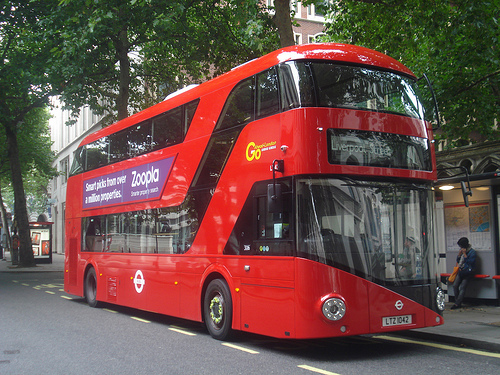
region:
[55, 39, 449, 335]
a red bus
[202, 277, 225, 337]
the front tire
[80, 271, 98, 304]
the back tire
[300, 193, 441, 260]
windshield on the bus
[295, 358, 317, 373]
the white line on the street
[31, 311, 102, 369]
the street is grey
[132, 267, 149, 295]
logo on the bus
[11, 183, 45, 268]
a tree trunk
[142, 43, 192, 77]
the leaves on the tree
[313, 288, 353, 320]
a headlight on the bus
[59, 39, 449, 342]
A double decker bus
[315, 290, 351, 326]
A headlight on a bus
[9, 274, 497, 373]
White lines on the road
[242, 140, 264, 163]
The word "Go" in yellow letters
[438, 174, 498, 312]
A person sitting at a bus stop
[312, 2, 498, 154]
Green leaves on a tree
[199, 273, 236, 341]
A black round tire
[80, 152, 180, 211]
A purple sign with white writing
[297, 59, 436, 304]
Reflections on the front bus windows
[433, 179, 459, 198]
A light is turned on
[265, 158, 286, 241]
the buses side view mirror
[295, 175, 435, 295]
the drivers front windshield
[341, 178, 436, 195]
the buses windshield wiper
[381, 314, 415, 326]
the buses license plate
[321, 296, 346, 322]
the buses round headlights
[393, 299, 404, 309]
the buses name brand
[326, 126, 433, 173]
the bus street name and route number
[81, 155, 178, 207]
an advertising banner displayed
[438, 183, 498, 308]
someone sitting on a bus bench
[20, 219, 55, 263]
a bus stop on the walkway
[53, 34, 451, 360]
A bus in the foreground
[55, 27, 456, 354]
The bus is red in color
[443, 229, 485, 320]
A person in the background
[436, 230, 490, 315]
Person is sitting down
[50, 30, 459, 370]
The bus is a double decker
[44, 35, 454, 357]
The bus is parked on the side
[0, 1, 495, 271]
Tall trees in the background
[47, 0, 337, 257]
Buildings in the background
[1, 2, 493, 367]
Photo was taken outdoors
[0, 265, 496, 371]
Concrete street is dark gray in color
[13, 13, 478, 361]
mode of transportation parked on the street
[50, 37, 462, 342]
a red double-decker bus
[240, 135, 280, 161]
logo/name of bus company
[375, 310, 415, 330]
vehicle's license plate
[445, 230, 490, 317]
person sitting in a waiting area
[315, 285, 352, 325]
one front headlight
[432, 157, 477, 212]
driver's side mirror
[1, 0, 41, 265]
tree on the sidewalk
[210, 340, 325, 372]
white traffic lines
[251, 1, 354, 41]
building behind the bus